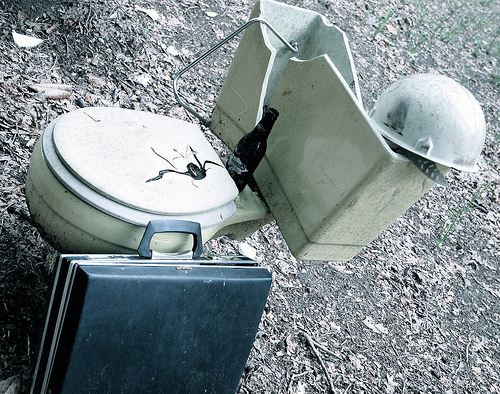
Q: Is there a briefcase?
A: Yes, there is a briefcase.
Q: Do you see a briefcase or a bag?
A: Yes, there is a briefcase.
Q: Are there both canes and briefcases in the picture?
A: No, there is a briefcase but no canes.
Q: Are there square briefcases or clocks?
A: Yes, there is a square briefcase.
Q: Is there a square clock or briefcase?
A: Yes, there is a square briefcase.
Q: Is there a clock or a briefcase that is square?
A: Yes, the briefcase is square.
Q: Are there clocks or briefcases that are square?
A: Yes, the briefcase is square.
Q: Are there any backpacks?
A: No, there are no backpacks.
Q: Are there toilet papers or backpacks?
A: No, there are no backpacks or toilet papers.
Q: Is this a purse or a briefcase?
A: This is a briefcase.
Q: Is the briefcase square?
A: Yes, the briefcase is square.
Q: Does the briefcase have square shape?
A: Yes, the briefcase is square.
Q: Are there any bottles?
A: Yes, there is a bottle.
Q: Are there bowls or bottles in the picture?
A: Yes, there is a bottle.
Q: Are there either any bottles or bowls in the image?
A: Yes, there is a bottle.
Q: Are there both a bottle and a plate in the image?
A: No, there is a bottle but no plates.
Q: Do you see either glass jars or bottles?
A: Yes, there is a glass bottle.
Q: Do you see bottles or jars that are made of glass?
A: Yes, the bottle is made of glass.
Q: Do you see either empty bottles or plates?
A: Yes, there is an empty bottle.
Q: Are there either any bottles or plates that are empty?
A: Yes, the bottle is empty.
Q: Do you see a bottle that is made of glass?
A: Yes, there is a bottle that is made of glass.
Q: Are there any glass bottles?
A: Yes, there is a bottle that is made of glass.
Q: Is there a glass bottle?
A: Yes, there is a bottle that is made of glass.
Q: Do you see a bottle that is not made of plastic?
A: Yes, there is a bottle that is made of glass.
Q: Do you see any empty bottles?
A: Yes, there is an empty bottle.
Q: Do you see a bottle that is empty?
A: Yes, there is a bottle that is empty.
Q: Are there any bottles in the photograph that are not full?
A: Yes, there is a empty bottle.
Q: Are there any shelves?
A: No, there are no shelves.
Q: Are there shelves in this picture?
A: No, there are no shelves.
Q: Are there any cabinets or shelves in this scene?
A: No, there are no shelves or cabinets.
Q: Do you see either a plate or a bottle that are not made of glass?
A: No, there is a bottle but it is made of glass.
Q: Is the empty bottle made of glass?
A: Yes, the bottle is made of glass.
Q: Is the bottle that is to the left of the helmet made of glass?
A: Yes, the bottle is made of glass.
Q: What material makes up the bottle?
A: The bottle is made of glass.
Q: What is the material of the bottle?
A: The bottle is made of glass.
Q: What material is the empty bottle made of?
A: The bottle is made of glass.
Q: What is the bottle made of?
A: The bottle is made of glass.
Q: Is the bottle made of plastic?
A: No, the bottle is made of glass.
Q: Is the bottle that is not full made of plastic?
A: No, the bottle is made of glass.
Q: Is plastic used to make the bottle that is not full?
A: No, the bottle is made of glass.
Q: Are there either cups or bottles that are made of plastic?
A: No, there is a bottle but it is made of glass.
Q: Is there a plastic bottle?
A: No, there is a bottle but it is made of glass.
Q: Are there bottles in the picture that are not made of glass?
A: No, there is a bottle but it is made of glass.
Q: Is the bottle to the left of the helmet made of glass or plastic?
A: The bottle is made of glass.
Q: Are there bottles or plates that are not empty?
A: No, there is a bottle but it is empty.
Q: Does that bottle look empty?
A: Yes, the bottle is empty.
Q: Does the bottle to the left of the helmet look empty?
A: Yes, the bottle is empty.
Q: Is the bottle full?
A: No, the bottle is empty.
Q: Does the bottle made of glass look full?
A: No, the bottle is empty.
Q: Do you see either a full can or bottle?
A: No, there is a bottle but it is empty.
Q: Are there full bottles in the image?
A: No, there is a bottle but it is empty.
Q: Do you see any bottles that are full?
A: No, there is a bottle but it is empty.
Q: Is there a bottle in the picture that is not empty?
A: No, there is a bottle but it is empty.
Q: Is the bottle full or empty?
A: The bottle is empty.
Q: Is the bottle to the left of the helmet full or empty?
A: The bottle is empty.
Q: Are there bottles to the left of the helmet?
A: Yes, there is a bottle to the left of the helmet.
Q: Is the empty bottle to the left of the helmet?
A: Yes, the bottle is to the left of the helmet.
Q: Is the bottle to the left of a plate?
A: No, the bottle is to the left of the helmet.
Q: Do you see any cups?
A: No, there are no cups.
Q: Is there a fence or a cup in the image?
A: No, there are no cups or fences.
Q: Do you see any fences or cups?
A: No, there are no cups or fences.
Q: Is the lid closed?
A: Yes, the lid is closed.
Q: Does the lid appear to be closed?
A: Yes, the lid is closed.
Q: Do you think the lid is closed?
A: Yes, the lid is closed.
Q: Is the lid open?
A: No, the lid is closed.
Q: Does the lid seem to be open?
A: No, the lid is closed.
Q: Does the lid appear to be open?
A: No, the lid is closed.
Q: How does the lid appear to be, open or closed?
A: The lid is closed.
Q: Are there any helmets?
A: Yes, there is a helmet.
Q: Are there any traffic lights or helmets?
A: Yes, there is a helmet.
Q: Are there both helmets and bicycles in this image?
A: No, there is a helmet but no bikes.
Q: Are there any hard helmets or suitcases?
A: Yes, there is a hard helmet.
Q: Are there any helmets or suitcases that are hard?
A: Yes, the helmet is hard.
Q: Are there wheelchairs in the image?
A: No, there are no wheelchairs.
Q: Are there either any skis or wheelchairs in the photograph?
A: No, there are no wheelchairs or skis.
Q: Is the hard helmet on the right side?
A: Yes, the helmet is on the right of the image.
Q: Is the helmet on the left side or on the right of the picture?
A: The helmet is on the right of the image.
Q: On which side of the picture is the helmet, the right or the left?
A: The helmet is on the right of the image.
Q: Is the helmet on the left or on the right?
A: The helmet is on the right of the image.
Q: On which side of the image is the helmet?
A: The helmet is on the right of the image.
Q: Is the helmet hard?
A: Yes, the helmet is hard.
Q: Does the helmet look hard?
A: Yes, the helmet is hard.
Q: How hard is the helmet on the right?
A: The helmet is hard.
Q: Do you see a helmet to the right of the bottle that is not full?
A: Yes, there is a helmet to the right of the bottle.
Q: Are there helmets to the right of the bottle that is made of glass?
A: Yes, there is a helmet to the right of the bottle.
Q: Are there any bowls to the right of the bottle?
A: No, there is a helmet to the right of the bottle.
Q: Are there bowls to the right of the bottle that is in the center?
A: No, there is a helmet to the right of the bottle.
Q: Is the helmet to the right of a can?
A: No, the helmet is to the right of a bottle.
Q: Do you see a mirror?
A: No, there are no mirrors.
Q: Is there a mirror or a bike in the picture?
A: No, there are no mirrors or bikes.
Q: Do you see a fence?
A: No, there are no fences.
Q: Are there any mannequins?
A: No, there are no mannequins.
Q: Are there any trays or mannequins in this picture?
A: No, there are no mannequins or trays.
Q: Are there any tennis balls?
A: No, there are no tennis balls.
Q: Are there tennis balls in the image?
A: No, there are no tennis balls.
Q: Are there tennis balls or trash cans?
A: No, there are no tennis balls or trash cans.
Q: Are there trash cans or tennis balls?
A: No, there are no tennis balls or trash cans.